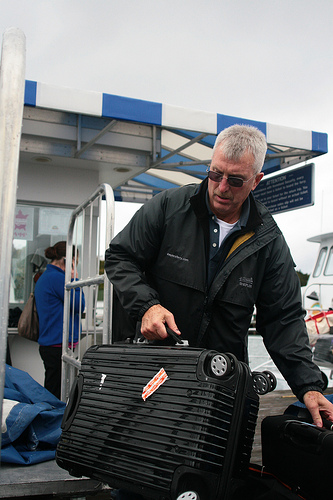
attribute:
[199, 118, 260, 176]
hair — gray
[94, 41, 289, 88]
sky — gray, white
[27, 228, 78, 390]
woman — standing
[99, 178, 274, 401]
windbreaker — black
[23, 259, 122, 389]
jacket — blue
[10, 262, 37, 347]
bag — brown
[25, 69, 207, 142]
roof — blue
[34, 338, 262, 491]
suitcase — black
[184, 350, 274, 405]
wheels — black